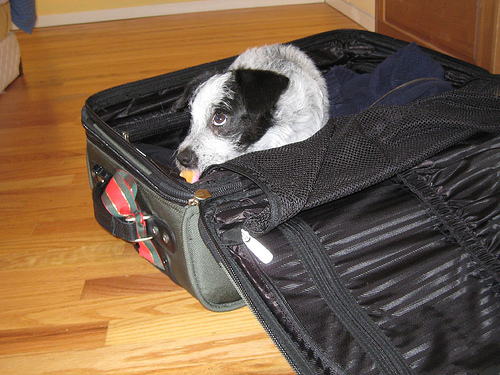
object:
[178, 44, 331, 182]
dog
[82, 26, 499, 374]
luggage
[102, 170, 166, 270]
ribbon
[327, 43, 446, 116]
clothes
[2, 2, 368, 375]
floor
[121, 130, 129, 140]
zipper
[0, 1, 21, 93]
mattress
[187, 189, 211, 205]
zipper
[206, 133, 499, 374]
cover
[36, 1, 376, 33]
trim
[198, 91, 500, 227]
divider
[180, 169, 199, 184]
toy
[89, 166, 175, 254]
handle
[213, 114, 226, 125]
eye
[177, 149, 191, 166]
nose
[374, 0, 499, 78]
door